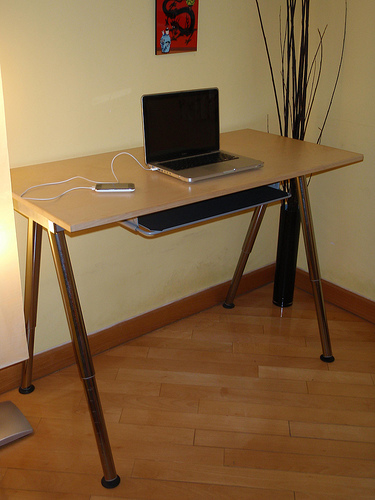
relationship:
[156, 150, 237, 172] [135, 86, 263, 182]
keyboard on laptop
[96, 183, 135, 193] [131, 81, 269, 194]
cell phone plugged laptop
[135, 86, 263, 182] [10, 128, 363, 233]
laptop on table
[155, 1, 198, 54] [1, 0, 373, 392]
artwork on wall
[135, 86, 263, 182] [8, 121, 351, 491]
laptop on a table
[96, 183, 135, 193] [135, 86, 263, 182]
cell phone plugged into a laptop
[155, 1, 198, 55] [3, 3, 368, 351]
artwork on wall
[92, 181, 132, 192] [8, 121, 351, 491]
cell phone on table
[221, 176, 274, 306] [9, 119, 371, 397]
leg of table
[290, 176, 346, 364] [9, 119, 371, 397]
leg of table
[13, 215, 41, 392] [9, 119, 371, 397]
leg of table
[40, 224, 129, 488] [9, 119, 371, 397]
leg of table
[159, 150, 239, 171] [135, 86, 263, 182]
keyboard of laptop